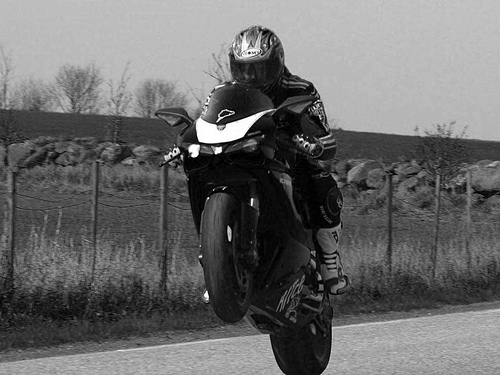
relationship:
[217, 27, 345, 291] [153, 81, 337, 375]
man on motorcycle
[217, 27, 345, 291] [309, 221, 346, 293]
man has boots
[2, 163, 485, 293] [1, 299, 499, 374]
posts are by road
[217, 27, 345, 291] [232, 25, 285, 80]
man has helmet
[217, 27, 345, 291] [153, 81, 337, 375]
man on a motorcycle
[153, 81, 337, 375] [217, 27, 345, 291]
motorcycle has man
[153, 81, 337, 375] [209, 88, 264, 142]
motorcycle has a windsheild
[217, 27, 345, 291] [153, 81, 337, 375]
man riding motorcycle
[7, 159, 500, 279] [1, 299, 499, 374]
fence by road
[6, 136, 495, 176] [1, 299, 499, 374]
rock wall by road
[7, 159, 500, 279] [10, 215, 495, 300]
fence has weeds